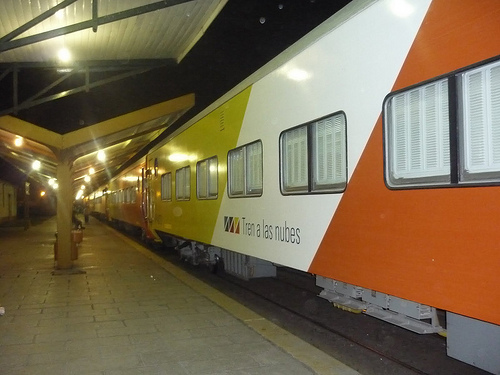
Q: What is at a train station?
A: A train.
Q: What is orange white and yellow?
A: Train.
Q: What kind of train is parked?
A: A passenger train.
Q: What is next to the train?
A: A sidewalk.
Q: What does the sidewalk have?
A: An awning.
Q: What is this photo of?
A: A train at night.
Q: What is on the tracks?
A: Train.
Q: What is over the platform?
A: Awning.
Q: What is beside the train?
A: Platform.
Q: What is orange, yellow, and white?
A: The train.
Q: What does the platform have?
A: Edge.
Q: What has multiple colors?
A: Train.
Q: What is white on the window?
A: Shutters.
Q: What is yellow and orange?
A: Passenger train.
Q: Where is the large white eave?
A: Straight forward.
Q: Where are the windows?
A: Along side of the train.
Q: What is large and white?
A: Overhang.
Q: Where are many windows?
A: On the train.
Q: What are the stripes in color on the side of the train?
A: Orange, yellow and white.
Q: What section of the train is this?
A: Orange section.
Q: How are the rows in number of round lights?
A: Two rows.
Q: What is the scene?
A: A train station at night.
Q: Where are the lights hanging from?
A: The ceiling.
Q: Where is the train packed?
A: In the station.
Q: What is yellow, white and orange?
A: The sleeper car.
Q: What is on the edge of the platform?
A: A yellow caution line.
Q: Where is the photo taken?
A: Train station.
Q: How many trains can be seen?
A: 1.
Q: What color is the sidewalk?
A: Gray.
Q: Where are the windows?
A: On train.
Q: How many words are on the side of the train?
A: 4.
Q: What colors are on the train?
A: Orange, yellow, white.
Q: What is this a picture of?
A: Train.